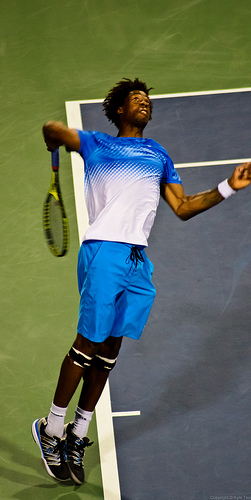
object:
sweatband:
[215, 176, 234, 203]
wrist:
[219, 179, 235, 202]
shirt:
[70, 127, 182, 251]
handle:
[50, 146, 59, 171]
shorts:
[75, 222, 156, 344]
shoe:
[61, 420, 93, 484]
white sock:
[45, 402, 68, 439]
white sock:
[72, 402, 96, 440]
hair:
[99, 74, 155, 132]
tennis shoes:
[30, 414, 72, 483]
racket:
[41, 136, 70, 260]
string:
[124, 243, 145, 286]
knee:
[64, 342, 91, 370]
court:
[0, 1, 251, 500]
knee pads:
[66, 343, 95, 373]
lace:
[76, 443, 85, 474]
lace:
[48, 440, 68, 470]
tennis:
[31, 75, 251, 486]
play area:
[64, 87, 251, 499]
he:
[30, 75, 250, 486]